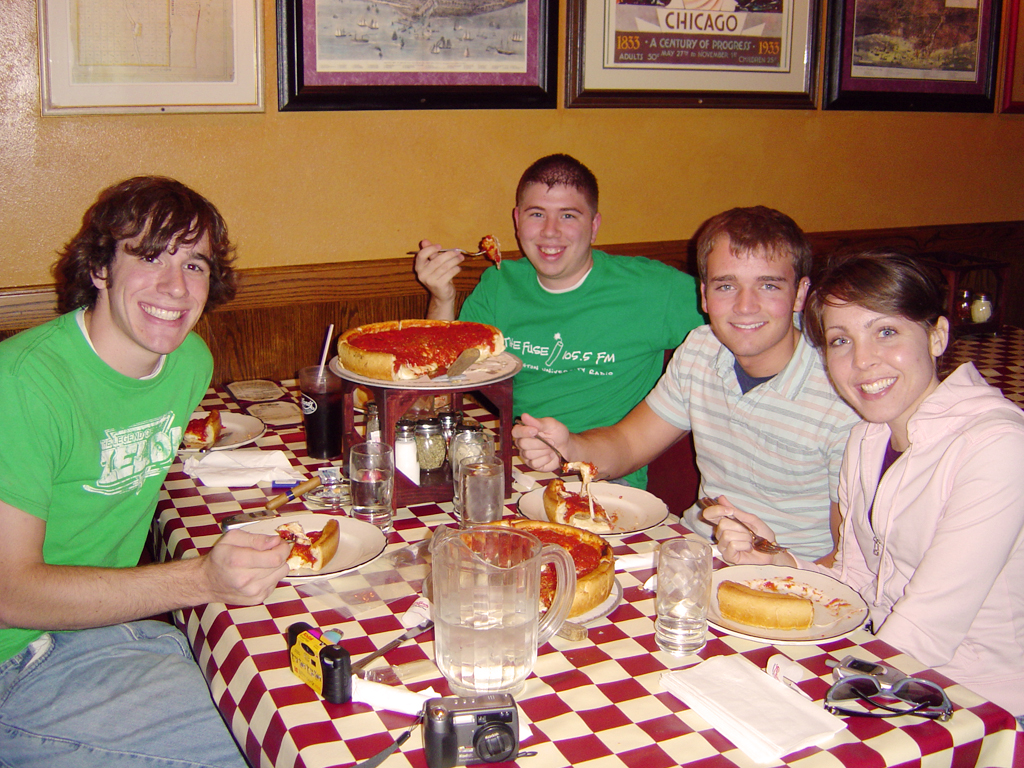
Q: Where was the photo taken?
A: At restaurant.